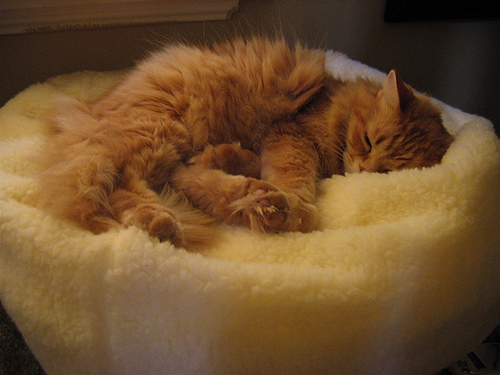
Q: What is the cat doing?
A: Sleeping.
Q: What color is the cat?
A: Orange/tannish.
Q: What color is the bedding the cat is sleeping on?
A: Yellow and white.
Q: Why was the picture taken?
A: To show cats gentle side.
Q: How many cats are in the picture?
A: One.